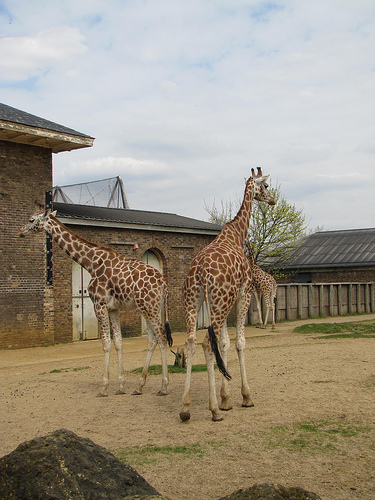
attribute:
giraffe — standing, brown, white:
[19, 203, 177, 397]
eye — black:
[29, 216, 37, 225]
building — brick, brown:
[53, 208, 240, 342]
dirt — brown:
[0, 315, 371, 494]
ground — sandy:
[0, 311, 373, 499]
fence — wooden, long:
[237, 278, 373, 329]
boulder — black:
[0, 430, 165, 499]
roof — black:
[55, 204, 220, 235]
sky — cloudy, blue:
[0, 5, 374, 232]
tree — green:
[214, 180, 308, 288]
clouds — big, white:
[102, 10, 260, 75]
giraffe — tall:
[179, 168, 277, 425]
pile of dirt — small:
[224, 484, 316, 500]